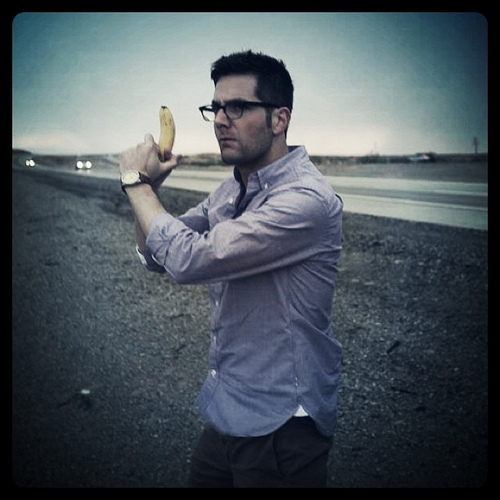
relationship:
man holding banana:
[125, 68, 341, 487] [148, 96, 177, 166]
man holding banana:
[125, 68, 341, 487] [156, 104, 174, 153]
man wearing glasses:
[125, 68, 341, 487] [143, 75, 275, 123]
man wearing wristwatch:
[125, 68, 341, 487] [119, 167, 154, 188]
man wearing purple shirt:
[125, 68, 341, 487] [146, 145, 346, 442]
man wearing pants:
[125, 68, 341, 487] [178, 410, 331, 499]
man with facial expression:
[125, 68, 341, 487] [201, 75, 263, 157]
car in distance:
[402, 147, 439, 164] [28, 110, 188, 228]